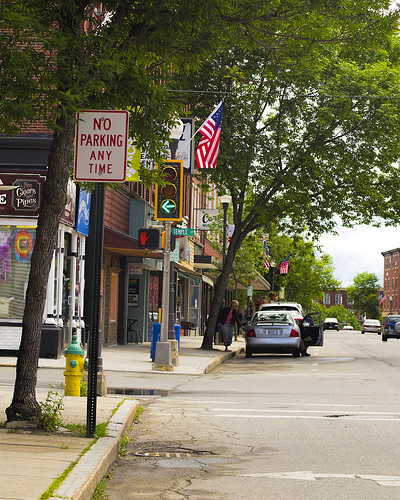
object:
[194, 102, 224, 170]
flag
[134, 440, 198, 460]
manhole cover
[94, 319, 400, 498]
street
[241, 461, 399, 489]
arrow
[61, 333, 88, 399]
fire hydrant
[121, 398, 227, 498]
cracks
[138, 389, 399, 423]
crosswalk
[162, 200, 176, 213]
arrow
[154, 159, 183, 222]
traffic light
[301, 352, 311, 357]
foot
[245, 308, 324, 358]
car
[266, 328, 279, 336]
license plate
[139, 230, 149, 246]
hand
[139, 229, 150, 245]
don't walk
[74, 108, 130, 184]
sign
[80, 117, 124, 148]
no parking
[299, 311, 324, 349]
door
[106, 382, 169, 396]
puddle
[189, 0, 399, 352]
tree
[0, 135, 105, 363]
store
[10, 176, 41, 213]
sign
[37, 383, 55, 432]
weeds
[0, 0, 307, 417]
tree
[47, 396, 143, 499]
curb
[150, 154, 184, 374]
post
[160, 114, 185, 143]
light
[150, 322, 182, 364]
trash can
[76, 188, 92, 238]
sign